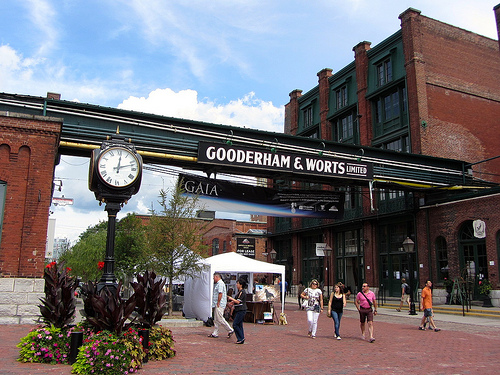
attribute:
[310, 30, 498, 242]
building — tall, brick, red, wide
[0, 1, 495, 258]
sky — white, blue, bright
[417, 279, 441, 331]
man — orange shirt, content, tall, thin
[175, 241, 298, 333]
tent — white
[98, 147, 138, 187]
clock — round, black, white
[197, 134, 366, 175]
sign — white, black, rectangular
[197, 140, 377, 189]
sign — rectangular,  white, black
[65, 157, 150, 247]
clock — black, white, round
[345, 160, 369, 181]
united word — small, white, rectangular, high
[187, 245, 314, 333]
tent — small, white, square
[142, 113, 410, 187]
sign — long, white, black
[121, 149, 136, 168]
numerals — black, small, thin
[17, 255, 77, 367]
flowers — green, pink,  bunched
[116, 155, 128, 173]
hands — thin, black, small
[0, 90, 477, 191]
bridge — black, long,  thin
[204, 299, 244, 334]
pants — beige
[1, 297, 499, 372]
tile — brick, red, wide, flat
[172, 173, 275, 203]
sign — black, white, dark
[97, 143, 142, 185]
clock — black, white, round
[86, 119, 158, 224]
clock —  tall, black, white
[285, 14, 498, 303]
building — red, brick, wide, tall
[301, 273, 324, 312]
person —  pink shirt, black shirt, white shirt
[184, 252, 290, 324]
tent — white,  square,  midsize, short, midsize